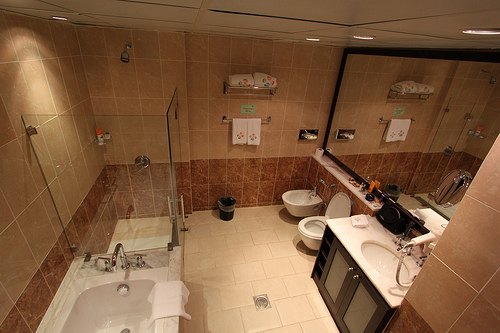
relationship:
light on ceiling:
[29, 4, 91, 45] [2, 0, 493, 50]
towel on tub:
[139, 278, 192, 324] [45, 245, 182, 332]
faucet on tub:
[88, 241, 148, 273] [36, 241, 191, 332]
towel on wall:
[231, 118, 261, 145] [176, 64, 330, 224]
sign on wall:
[239, 99, 264, 118] [78, 29, 318, 209]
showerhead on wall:
[119, 40, 134, 63] [79, 25, 186, 214]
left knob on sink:
[390, 227, 411, 244] [337, 205, 421, 302]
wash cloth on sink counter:
[350, 212, 368, 229] [325, 213, 422, 309]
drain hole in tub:
[120, 327, 132, 331] [36, 241, 191, 332]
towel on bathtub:
[139, 278, 192, 324] [39, 241, 184, 331]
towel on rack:
[223, 68, 253, 95] [222, 67, 277, 99]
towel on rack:
[251, 67, 278, 94] [222, 67, 277, 99]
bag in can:
[213, 195, 243, 210] [208, 182, 241, 227]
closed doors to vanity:
[312, 240, 391, 333] [312, 205, 419, 330]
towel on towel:
[226, 73, 255, 86] [253, 71, 277, 87]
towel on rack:
[253, 71, 277, 87] [222, 70, 276, 98]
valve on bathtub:
[92, 253, 114, 274] [30, 247, 182, 332]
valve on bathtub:
[128, 252, 153, 271] [30, 247, 182, 332]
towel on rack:
[231, 118, 261, 145] [219, 116, 271, 122]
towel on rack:
[231, 118, 261, 145] [220, 116, 275, 124]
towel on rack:
[228, 116, 261, 148] [219, 114, 276, 124]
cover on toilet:
[324, 189, 351, 217] [297, 189, 352, 249]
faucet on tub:
[106, 241, 136, 275] [36, 241, 191, 332]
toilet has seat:
[297, 189, 352, 249] [297, 188, 352, 240]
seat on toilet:
[297, 188, 352, 240] [297, 189, 352, 249]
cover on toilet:
[324, 189, 354, 221] [293, 188, 351, 248]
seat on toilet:
[296, 194, 351, 240] [281, 177, 376, 279]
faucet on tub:
[88, 241, 148, 273] [48, 251, 200, 331]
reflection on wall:
[24, 51, 62, 122] [11, 5, 114, 330]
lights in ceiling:
[297, 30, 323, 46] [2, 0, 493, 50]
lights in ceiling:
[342, 29, 378, 46] [2, 0, 493, 50]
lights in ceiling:
[458, 23, 498, 42] [2, 0, 493, 50]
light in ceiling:
[47, 14, 73, 22] [2, 0, 493, 50]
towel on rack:
[231, 118, 261, 145] [219, 110, 273, 128]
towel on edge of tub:
[139, 275, 193, 324] [58, 196, 206, 331]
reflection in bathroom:
[318, 53, 495, 200] [7, 2, 498, 325]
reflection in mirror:
[318, 53, 495, 200] [321, 46, 496, 240]